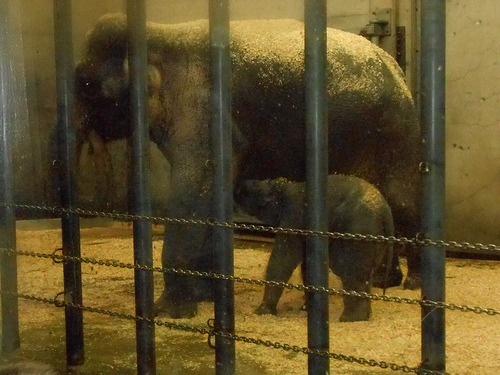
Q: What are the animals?
A: Elephants.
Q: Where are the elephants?
A: In a cage.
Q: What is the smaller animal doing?
A: Nursing.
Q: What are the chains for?
A: To enclose the animals.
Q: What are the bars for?
A: To enclose the animals.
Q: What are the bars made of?
A: Metal.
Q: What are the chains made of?
A: Metal.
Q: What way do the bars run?
A: Vertically.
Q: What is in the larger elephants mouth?
A: The trunk.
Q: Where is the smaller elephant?
A: Under the larger one.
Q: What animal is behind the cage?
A: Elephant.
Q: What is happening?
A: Large elephant feeding small elephant.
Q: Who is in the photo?
A: Adult and baby elephant.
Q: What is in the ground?
A: Bars in the foreground.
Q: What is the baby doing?
A: Baby elephant is nursing.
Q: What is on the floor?
A: Hay and dust on the floor.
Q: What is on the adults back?
A: Adult has hay on its back.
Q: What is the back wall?
A: Back wall is concrete.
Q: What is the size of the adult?
A: Adult elephant is bigger than the baby.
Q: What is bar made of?
A: Metal.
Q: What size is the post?
A: Large.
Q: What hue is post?
A: Gray.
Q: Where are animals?
A: Behind post.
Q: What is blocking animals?
A: Post.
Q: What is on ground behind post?
A: Hay.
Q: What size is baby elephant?
A: Small.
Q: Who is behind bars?
A: Elephants.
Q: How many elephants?
A: Two.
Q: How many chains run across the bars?
A: Three.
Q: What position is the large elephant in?
A: Standing.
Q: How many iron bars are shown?
A: Six.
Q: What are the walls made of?
A: Concrete.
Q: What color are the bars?
A: Black.